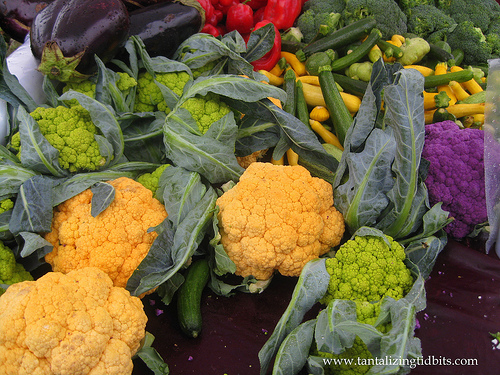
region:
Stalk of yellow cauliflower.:
[216, 157, 345, 280]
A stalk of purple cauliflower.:
[414, 120, 499, 240]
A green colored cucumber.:
[174, 254, 214, 338]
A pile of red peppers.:
[197, 1, 306, 70]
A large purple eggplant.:
[26, 0, 130, 82]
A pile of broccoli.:
[282, 0, 499, 62]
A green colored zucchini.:
[316, 63, 355, 146]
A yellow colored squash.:
[422, 85, 449, 110]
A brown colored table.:
[132, 270, 297, 374]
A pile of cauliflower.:
[0, 62, 499, 374]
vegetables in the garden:
[2, 50, 479, 345]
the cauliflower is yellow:
[12, 300, 87, 353]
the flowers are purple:
[435, 138, 480, 208]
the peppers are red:
[265, 14, 286, 39]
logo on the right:
[307, 345, 492, 365]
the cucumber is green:
[333, 27, 372, 42]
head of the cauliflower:
[234, 191, 348, 223]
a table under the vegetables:
[432, 252, 493, 367]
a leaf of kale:
[352, 63, 414, 208]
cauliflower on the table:
[213, 164, 328, 268]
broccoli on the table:
[380, 18, 489, 33]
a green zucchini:
[320, 71, 362, 141]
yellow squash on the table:
[434, 87, 474, 122]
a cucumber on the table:
[173, 243, 201, 332]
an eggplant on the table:
[24, 18, 206, 60]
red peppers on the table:
[201, 1, 296, 56]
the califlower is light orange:
[268, 199, 290, 227]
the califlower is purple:
[443, 151, 470, 197]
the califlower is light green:
[53, 113, 69, 128]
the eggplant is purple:
[59, 15, 84, 38]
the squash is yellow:
[308, 86, 325, 102]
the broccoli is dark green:
[421, 12, 443, 26]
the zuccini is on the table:
[178, 318, 209, 341]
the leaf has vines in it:
[389, 95, 408, 124]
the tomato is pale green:
[406, 40, 421, 57]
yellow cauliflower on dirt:
[19, 190, 295, 350]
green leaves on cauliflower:
[1, 143, 202, 237]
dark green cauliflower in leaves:
[307, 234, 415, 344]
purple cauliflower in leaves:
[433, 112, 478, 227]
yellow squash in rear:
[273, 51, 471, 131]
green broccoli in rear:
[322, 3, 487, 66]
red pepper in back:
[191, 1, 295, 61]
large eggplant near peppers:
[2, 7, 211, 43]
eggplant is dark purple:
[28, 13, 192, 66]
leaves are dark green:
[5, 112, 212, 317]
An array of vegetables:
[5, 2, 495, 371]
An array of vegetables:
[51, 70, 269, 260]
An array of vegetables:
[251, 23, 481, 209]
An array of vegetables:
[45, 56, 401, 304]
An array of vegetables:
[43, 65, 316, 273]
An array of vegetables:
[116, 51, 424, 286]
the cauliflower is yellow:
[215, 158, 345, 279]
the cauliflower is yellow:
[43, 176, 166, 301]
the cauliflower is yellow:
[0, 265, 148, 372]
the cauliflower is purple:
[421, 120, 499, 238]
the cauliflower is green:
[309, 233, 411, 372]